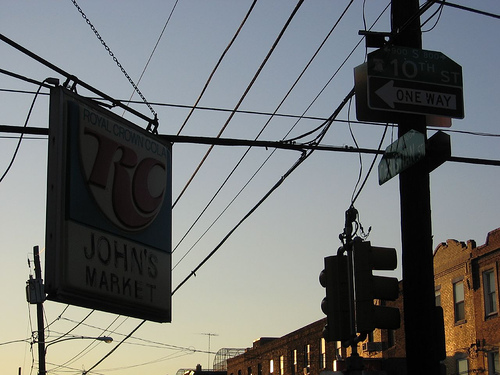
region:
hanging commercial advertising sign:
[40, 80, 176, 325]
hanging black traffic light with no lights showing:
[315, 210, 407, 347]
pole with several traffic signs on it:
[351, 35, 470, 356]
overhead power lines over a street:
[164, 30, 343, 196]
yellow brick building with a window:
[431, 234, 490, 357]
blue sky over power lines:
[174, 0, 346, 207]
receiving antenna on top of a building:
[191, 322, 224, 372]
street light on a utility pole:
[34, 327, 119, 354]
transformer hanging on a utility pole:
[15, 243, 52, 313]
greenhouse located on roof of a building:
[206, 343, 254, 366]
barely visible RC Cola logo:
[86, 127, 168, 228]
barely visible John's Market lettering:
[83, 237, 168, 301]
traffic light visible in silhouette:
[314, 207, 401, 344]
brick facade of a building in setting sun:
[436, 226, 498, 371]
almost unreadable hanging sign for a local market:
[44, 85, 170, 323]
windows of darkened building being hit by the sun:
[269, 340, 349, 373]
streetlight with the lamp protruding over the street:
[26, 245, 115, 371]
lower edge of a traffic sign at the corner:
[353, 75, 465, 126]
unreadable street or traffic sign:
[377, 129, 452, 185]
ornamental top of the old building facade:
[436, 230, 497, 271]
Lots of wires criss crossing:
[1, 0, 496, 372]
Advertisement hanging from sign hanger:
[46, 83, 178, 327]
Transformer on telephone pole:
[23, 275, 48, 307]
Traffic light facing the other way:
[318, 232, 406, 352]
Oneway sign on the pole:
[362, 73, 465, 122]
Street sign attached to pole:
[366, 41, 468, 90]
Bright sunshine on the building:
[325, 226, 497, 373]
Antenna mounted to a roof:
[198, 329, 220, 370]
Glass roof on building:
[212, 345, 251, 371]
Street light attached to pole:
[46, 334, 115, 350]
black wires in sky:
[2, 3, 360, 370]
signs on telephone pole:
[353, 1, 465, 372]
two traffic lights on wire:
[320, 150, 397, 341]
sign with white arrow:
[364, 73, 466, 118]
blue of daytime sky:
[5, 4, 495, 276]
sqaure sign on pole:
[1, 29, 177, 323]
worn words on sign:
[43, 219, 174, 323]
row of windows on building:
[235, 235, 497, 372]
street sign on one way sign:
[364, 41, 461, 117]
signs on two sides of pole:
[377, 130, 454, 250]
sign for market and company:
[43, 76, 175, 319]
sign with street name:
[362, 41, 473, 83]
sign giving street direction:
[362, 78, 466, 120]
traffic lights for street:
[310, 235, 402, 343]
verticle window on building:
[479, 262, 499, 319]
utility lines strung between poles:
[176, 9, 322, 144]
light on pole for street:
[43, 333, 117, 353]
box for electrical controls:
[25, 273, 50, 303]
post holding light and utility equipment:
[30, 243, 50, 373]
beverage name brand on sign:
[75, 105, 170, 236]